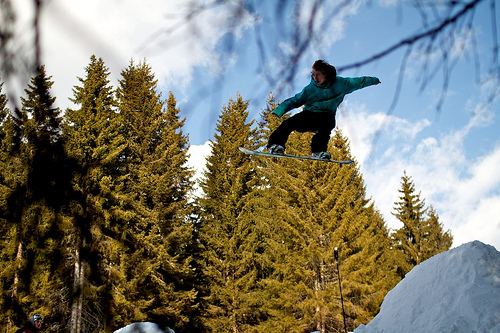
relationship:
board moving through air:
[238, 144, 354, 166] [416, 94, 457, 129]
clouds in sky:
[1, 2, 498, 255] [1, 1, 498, 247]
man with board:
[268, 60, 382, 162] [238, 144, 354, 166]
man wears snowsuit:
[268, 60, 382, 162] [273, 77, 383, 153]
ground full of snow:
[337, 240, 500, 333] [405, 266, 499, 303]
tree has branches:
[135, 2, 498, 104] [331, 2, 499, 92]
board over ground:
[238, 144, 354, 166] [337, 240, 497, 330]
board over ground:
[238, 144, 354, 166] [105, 319, 183, 331]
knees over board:
[266, 109, 334, 160] [239, 141, 353, 172]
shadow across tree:
[16, 114, 128, 209] [6, 55, 144, 320]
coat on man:
[271, 75, 383, 118] [268, 60, 382, 162]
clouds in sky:
[366, 137, 450, 187] [381, 72, 445, 144]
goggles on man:
[307, 73, 333, 85] [255, 61, 380, 166]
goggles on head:
[307, 73, 333, 85] [309, 61, 337, 88]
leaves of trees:
[181, 192, 306, 259] [3, 62, 429, 331]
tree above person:
[58, 64, 235, 324] [254, 40, 400, 234]